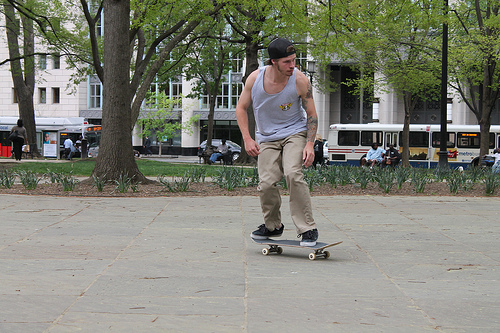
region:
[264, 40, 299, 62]
a man's black baseball cap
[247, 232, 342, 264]
a long black skateboard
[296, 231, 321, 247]
a man's tennis shoe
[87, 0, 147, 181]
a tall tree branch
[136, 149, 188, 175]
a section of green grass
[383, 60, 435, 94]
green tree leaves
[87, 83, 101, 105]
a window of a building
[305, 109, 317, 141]
a man's arm tattoo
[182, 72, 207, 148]
part of a white building column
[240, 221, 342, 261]
feet on skateboard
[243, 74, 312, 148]
tank top on person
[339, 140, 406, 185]
people sitting on a bench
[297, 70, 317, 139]
tattoos on the arm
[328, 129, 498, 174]
bus on the street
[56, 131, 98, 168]
people getting on the bus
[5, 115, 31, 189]
woman walking toward street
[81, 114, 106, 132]
destination on the bus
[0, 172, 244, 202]
green leaves on the ground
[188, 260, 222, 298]
part of a floor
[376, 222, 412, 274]
part of a floor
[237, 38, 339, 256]
man crouching on a skateboard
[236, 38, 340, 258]
young man crouching on a skateboard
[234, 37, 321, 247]
man in a muscle shirt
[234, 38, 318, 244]
young man in a muscle shirt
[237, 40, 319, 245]
man in a backward ball cap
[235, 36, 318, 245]
young man in a backward ball cap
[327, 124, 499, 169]
bus headed to the right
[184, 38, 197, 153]
large column on a building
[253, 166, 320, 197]
bent knees of a skateboarder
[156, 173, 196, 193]
plant in a garden area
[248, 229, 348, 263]
Man on a board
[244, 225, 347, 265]
Man is on a board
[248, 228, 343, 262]
Man on a skateboard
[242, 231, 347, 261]
Man is on a skateboard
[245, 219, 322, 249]
Man wearing shoes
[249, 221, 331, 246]
Man is wearing shoes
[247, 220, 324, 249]
Man wearing black and white shoes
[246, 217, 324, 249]
Man is wearing black and white shoes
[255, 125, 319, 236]
Man wearing pants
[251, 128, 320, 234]
Man is wearing pants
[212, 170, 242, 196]
A shrub in the ground.